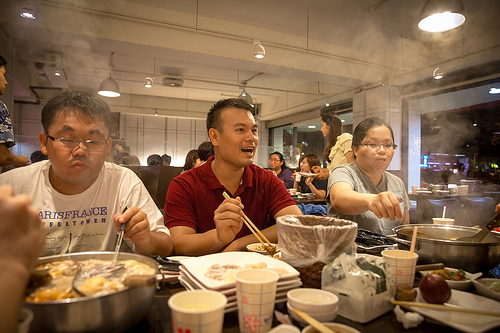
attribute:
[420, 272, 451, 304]
apple — red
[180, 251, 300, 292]
plate — stacked, square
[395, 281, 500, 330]
plate — white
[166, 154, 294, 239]
shirt — red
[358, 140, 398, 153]
glasses — pair, on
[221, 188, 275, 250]
chopstick — wooden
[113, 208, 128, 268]
spoon — metal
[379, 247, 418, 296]
paper cup — designed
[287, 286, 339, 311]
bowl — stacked, small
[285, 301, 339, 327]
bowl — small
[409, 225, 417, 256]
straw — light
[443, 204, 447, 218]
straw — light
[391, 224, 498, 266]
pot — silver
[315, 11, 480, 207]
steam — rising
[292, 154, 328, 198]
woman — seated, sipping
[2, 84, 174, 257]
person — looking, seated, sitting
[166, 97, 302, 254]
person — sitting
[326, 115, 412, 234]
person — sitting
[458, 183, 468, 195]
cup — plastic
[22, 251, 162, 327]
bowl — full, bowled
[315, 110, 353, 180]
waitress — female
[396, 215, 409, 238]
utensil — stirred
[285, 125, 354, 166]
window — large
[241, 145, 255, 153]
mouth — opened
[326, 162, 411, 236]
shirt — grey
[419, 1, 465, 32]
light — on